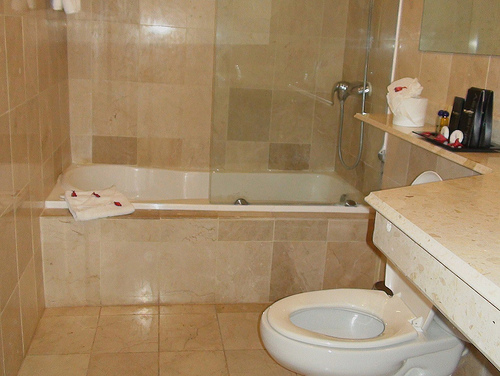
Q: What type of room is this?
A: It is a bathroom.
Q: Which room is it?
A: It is a bathroom.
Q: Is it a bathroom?
A: Yes, it is a bathroom.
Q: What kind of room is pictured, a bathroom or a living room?
A: It is a bathroom.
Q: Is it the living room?
A: No, it is the bathroom.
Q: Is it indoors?
A: Yes, it is indoors.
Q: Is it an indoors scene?
A: Yes, it is indoors.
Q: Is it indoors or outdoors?
A: It is indoors.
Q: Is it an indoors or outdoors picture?
A: It is indoors.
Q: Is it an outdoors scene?
A: No, it is indoors.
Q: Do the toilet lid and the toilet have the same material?
A: Yes, both the lid and the toilet are made of plastic.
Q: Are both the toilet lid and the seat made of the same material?
A: Yes, both the lid and the seat are made of plastic.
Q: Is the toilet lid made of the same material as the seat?
A: Yes, both the lid and the seat are made of plastic.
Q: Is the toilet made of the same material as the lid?
A: Yes, both the toilet and the lid are made of plastic.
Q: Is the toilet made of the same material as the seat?
A: Yes, both the toilet and the seat are made of plastic.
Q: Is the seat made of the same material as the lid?
A: Yes, both the seat and the lid are made of plastic.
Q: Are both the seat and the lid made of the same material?
A: Yes, both the seat and the lid are made of plastic.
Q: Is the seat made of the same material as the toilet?
A: Yes, both the seat and the toilet are made of plastic.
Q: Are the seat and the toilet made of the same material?
A: Yes, both the seat and the toilet are made of plastic.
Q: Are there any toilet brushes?
A: No, there are no toilet brushes.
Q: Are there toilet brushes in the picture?
A: No, there are no toilet brushes.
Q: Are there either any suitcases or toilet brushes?
A: No, there are no toilet brushes or suitcases.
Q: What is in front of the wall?
A: The bathtub is in front of the wall.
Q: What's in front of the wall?
A: The bathtub is in front of the wall.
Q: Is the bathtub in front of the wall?
A: Yes, the bathtub is in front of the wall.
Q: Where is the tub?
A: The tub is in the bathroom.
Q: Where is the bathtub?
A: The tub is in the bathroom.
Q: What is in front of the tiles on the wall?
A: The bathtub is in front of the tiles.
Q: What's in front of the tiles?
A: The bathtub is in front of the tiles.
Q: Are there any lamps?
A: No, there are no lamps.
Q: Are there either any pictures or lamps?
A: No, there are no lamps or pictures.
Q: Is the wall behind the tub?
A: Yes, the wall is behind the tub.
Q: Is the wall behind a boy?
A: No, the wall is behind the tub.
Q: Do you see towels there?
A: Yes, there is a towel.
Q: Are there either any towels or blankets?
A: Yes, there is a towel.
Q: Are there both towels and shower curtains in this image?
A: No, there is a towel but no shower curtains.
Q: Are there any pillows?
A: No, there are no pillows.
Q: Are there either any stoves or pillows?
A: No, there are no pillows or stoves.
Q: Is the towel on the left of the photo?
A: Yes, the towel is on the left of the image.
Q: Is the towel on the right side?
A: No, the towel is on the left of the image.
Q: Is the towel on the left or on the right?
A: The towel is on the left of the image.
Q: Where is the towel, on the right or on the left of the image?
A: The towel is on the left of the image.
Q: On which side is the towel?
A: The towel is on the left of the image.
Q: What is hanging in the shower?
A: The towel is hanging in the shower.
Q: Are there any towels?
A: Yes, there is a towel.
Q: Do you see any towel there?
A: Yes, there is a towel.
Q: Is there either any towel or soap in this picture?
A: Yes, there is a towel.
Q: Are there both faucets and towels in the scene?
A: Yes, there are both a towel and a faucet.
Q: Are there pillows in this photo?
A: No, there are no pillows.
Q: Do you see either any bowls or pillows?
A: No, there are no pillows or bowls.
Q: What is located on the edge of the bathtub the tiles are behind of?
A: The towel is on the edge of the bathtub.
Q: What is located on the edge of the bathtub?
A: The towel is on the edge of the bathtub.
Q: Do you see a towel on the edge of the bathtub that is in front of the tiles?
A: Yes, there is a towel on the edge of the bath tub.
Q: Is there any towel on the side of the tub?
A: Yes, there is a towel on the side of the tub.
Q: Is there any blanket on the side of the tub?
A: No, there is a towel on the side of the tub.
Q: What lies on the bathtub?
A: The towel lies on the bath tub.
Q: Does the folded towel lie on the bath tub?
A: Yes, the towel lies on the bath tub.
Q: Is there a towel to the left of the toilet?
A: Yes, there is a towel to the left of the toilet.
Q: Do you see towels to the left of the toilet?
A: Yes, there is a towel to the left of the toilet.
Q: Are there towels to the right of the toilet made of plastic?
A: No, the towel is to the left of the toilet.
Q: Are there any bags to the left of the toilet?
A: No, there is a towel to the left of the toilet.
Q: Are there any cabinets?
A: No, there are no cabinets.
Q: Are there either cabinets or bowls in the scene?
A: No, there are no cabinets or bowls.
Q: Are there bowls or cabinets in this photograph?
A: No, there are no cabinets or bowls.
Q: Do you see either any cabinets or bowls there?
A: No, there are no cabinets or bowls.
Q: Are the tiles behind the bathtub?
A: Yes, the tiles are behind the bathtub.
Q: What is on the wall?
A: The tiles are on the wall.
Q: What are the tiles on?
A: The tiles are on the wall.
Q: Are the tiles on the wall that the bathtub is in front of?
A: Yes, the tiles are on the wall.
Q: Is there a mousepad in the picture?
A: No, there are no mouse pads.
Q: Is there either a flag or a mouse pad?
A: No, there are no mouse pads or flags.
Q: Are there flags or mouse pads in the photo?
A: No, there are no mouse pads or flags.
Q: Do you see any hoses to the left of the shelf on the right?
A: Yes, there is a hose to the left of the shelf.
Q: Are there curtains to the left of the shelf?
A: No, there is a hose to the left of the shelf.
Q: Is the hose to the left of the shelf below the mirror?
A: Yes, the hose is to the left of the shelf.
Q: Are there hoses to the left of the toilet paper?
A: Yes, there is a hose to the left of the toilet paper.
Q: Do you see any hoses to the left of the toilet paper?
A: Yes, there is a hose to the left of the toilet paper.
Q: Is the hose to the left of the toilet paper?
A: Yes, the hose is to the left of the toilet paper.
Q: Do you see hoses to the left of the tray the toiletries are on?
A: Yes, there is a hose to the left of the tray.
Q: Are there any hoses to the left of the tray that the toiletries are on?
A: Yes, there is a hose to the left of the tray.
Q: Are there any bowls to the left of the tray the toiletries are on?
A: No, there is a hose to the left of the tray.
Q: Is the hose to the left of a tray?
A: Yes, the hose is to the left of a tray.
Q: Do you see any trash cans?
A: No, there are no trash cans.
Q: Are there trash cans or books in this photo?
A: No, there are no trash cans or books.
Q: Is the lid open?
A: Yes, the lid is open.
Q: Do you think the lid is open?
A: Yes, the lid is open.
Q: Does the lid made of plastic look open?
A: Yes, the lid is open.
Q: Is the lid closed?
A: No, the lid is open.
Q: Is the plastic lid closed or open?
A: The lid is open.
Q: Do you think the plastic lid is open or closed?
A: The lid is open.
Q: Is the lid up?
A: Yes, the lid is up.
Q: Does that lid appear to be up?
A: Yes, the lid is up.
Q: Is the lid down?
A: No, the lid is up.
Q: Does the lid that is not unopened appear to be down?
A: No, the lid is up.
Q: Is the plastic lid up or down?
A: The lid is up.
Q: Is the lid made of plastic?
A: Yes, the lid is made of plastic.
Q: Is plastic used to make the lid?
A: Yes, the lid is made of plastic.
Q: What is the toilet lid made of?
A: The lid is made of plastic.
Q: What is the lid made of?
A: The lid is made of plastic.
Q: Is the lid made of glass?
A: No, the lid is made of plastic.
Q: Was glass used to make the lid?
A: No, the lid is made of plastic.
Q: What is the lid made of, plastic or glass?
A: The lid is made of plastic.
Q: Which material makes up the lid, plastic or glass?
A: The lid is made of plastic.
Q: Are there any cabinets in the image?
A: No, there are no cabinets.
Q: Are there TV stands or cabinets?
A: No, there are no cabinets or TV stands.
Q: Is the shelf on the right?
A: Yes, the shelf is on the right of the image.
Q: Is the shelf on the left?
A: No, the shelf is on the right of the image.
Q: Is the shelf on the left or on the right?
A: The shelf is on the right of the image.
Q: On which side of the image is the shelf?
A: The shelf is on the right of the image.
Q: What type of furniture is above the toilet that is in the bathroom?
A: The piece of furniture is a shelf.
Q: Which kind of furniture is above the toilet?
A: The piece of furniture is a shelf.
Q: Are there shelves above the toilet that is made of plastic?
A: Yes, there is a shelf above the toilet.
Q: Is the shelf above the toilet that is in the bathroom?
A: Yes, the shelf is above the toilet.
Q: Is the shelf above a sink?
A: No, the shelf is above the toilet.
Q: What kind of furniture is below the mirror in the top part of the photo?
A: The piece of furniture is a shelf.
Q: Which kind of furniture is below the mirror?
A: The piece of furniture is a shelf.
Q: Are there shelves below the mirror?
A: Yes, there is a shelf below the mirror.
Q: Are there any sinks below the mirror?
A: No, there is a shelf below the mirror.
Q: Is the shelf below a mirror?
A: Yes, the shelf is below a mirror.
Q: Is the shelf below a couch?
A: No, the shelf is below a mirror.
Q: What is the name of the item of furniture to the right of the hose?
A: The piece of furniture is a shelf.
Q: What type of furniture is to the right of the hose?
A: The piece of furniture is a shelf.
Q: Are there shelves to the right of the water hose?
A: Yes, there is a shelf to the right of the water hose.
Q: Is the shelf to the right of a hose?
A: Yes, the shelf is to the right of a hose.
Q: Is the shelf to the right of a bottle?
A: No, the shelf is to the right of a hose.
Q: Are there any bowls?
A: No, there are no bowls.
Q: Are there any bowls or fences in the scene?
A: No, there are no bowls or fences.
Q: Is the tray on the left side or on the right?
A: The tray is on the right of the image.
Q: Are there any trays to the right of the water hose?
A: Yes, there is a tray to the right of the water hose.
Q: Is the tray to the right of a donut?
A: No, the tray is to the right of a hose.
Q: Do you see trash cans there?
A: No, there are no trash cans.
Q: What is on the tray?
A: The toiletries are on the tray.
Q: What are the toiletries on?
A: The toiletries are on the tray.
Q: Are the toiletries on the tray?
A: Yes, the toiletries are on the tray.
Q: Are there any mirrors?
A: Yes, there is a mirror.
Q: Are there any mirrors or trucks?
A: Yes, there is a mirror.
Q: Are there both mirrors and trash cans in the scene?
A: No, there is a mirror but no trash cans.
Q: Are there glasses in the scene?
A: No, there are no glasses.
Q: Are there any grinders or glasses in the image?
A: No, there are no glasses or grinders.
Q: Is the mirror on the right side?
A: Yes, the mirror is on the right of the image.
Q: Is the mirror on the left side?
A: No, the mirror is on the right of the image.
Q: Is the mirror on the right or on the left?
A: The mirror is on the right of the image.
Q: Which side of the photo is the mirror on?
A: The mirror is on the right of the image.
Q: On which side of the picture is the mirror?
A: The mirror is on the right of the image.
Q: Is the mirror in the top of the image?
A: Yes, the mirror is in the top of the image.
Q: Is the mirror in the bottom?
A: No, the mirror is in the top of the image.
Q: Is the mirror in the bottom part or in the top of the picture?
A: The mirror is in the top of the image.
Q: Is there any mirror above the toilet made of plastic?
A: Yes, there is a mirror above the toilet.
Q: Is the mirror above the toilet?
A: Yes, the mirror is above the toilet.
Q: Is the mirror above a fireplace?
A: No, the mirror is above the toilet.